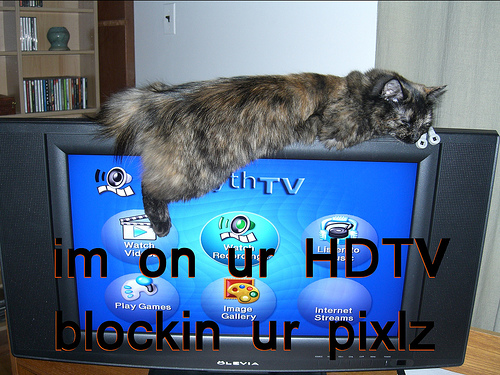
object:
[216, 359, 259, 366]
brand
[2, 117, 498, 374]
television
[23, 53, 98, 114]
shelf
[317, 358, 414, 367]
control panel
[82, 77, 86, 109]
cd covers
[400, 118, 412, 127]
eye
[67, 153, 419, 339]
screen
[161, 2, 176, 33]
switch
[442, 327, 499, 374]
wood flooring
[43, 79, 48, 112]
dvds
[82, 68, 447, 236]
cat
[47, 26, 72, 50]
vase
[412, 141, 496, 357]
speaker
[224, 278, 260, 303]
icon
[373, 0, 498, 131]
curtain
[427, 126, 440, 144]
headphones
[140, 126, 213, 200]
leg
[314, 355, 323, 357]
buttons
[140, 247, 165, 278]
words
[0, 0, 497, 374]
photo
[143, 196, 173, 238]
cat foot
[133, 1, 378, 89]
wall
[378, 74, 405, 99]
ear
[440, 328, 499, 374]
floor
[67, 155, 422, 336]
digital display